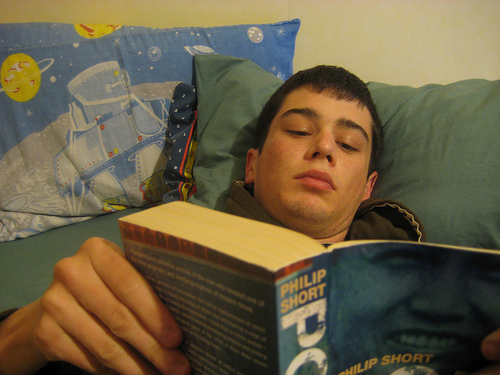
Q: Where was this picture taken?
A: A bedroom.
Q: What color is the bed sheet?
A: Green.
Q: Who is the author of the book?
A: Phillip Short.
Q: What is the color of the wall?
A: White.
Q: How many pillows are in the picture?
A: Three.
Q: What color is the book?
A: Blue.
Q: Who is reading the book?
A: A man.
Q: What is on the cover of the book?
A: A face.